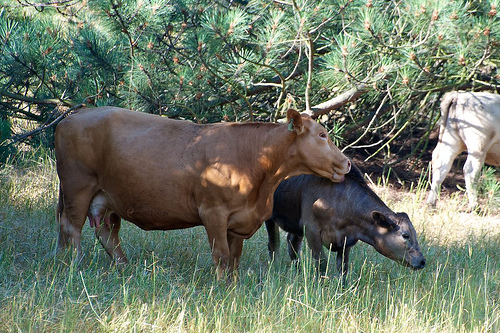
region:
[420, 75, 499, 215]
cow in a field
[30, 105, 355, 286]
cow in a field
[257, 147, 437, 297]
cow in a field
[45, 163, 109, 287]
leg of a cow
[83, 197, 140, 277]
leg of a cow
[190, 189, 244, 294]
leg of a cow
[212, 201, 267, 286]
leg of a cow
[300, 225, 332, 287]
leg of a cow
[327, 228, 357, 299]
leg of a cow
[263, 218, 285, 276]
leg of a cow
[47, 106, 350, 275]
a large brown cow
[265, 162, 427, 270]
a small dark brown cow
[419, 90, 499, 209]
a large white cow in a field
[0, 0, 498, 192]
a large pine tree in the distance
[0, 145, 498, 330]
a field of tall grass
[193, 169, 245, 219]
a cows haunch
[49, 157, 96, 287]
a cows rear leg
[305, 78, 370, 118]
a large branch on a pine tree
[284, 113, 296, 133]
a tag on a cows ear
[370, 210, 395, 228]
a cows ear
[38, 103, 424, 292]
two cows standing together in the grass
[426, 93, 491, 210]
another cow standing over by the trees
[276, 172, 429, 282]
a cute little baby cow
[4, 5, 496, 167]
a big pine tree behind the cows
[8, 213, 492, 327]
the tall grass around the cows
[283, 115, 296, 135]
the tag on the cows ear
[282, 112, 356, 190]
a happy looking cow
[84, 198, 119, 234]
the udders on the bigger cow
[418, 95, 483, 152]
branch shadows on the tree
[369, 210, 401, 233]
the ear on the baby cow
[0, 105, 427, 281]
Cows grazing in the grass.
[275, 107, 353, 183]
Head of a cow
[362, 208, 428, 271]
Head of a baby cow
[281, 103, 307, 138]
Cow ear with green tag in it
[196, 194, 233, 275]
Right front leg of a cow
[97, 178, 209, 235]
Belly of a brown cow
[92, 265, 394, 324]
Green grassy field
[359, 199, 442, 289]
Baby cow grazing on grass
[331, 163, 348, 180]
Mouth of brown cow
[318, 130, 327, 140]
Eye of brown cow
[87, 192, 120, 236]
Utter of brown cow